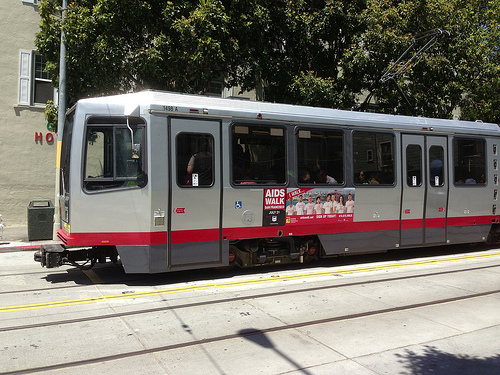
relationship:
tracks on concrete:
[1, 261, 483, 370] [0, 253, 496, 372]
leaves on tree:
[43, 3, 485, 115] [40, 0, 486, 102]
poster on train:
[263, 186, 355, 226] [35, 92, 492, 272]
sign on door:
[191, 170, 199, 188] [167, 115, 223, 267]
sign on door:
[410, 172, 416, 185] [398, 131, 425, 245]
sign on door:
[433, 174, 440, 187] [421, 130, 449, 246]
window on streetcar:
[87, 120, 144, 185] [37, 86, 497, 271]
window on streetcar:
[176, 131, 215, 188] [37, 86, 497, 271]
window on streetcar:
[227, 117, 291, 185] [37, 86, 497, 271]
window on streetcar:
[292, 125, 350, 186] [37, 86, 497, 271]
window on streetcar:
[351, 130, 398, 186] [37, 86, 497, 271]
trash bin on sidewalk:
[25, 199, 55, 243] [6, 233, 100, 246]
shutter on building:
[15, 46, 35, 110] [3, 0, 274, 243]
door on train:
[398, 131, 428, 248] [35, 92, 492, 272]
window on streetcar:
[172, 131, 220, 191] [37, 86, 497, 271]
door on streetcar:
[167, 115, 223, 267] [37, 86, 497, 271]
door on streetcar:
[398, 124, 428, 248] [37, 86, 497, 271]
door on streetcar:
[426, 131, 451, 247] [37, 86, 497, 271]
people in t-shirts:
[297, 195, 330, 212] [285, 201, 298, 212]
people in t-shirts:
[297, 195, 330, 212] [295, 198, 306, 218]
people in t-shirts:
[297, 195, 330, 212] [303, 201, 316, 218]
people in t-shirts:
[297, 195, 330, 212] [315, 202, 324, 216]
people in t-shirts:
[297, 195, 330, 212] [343, 200, 357, 214]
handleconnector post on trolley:
[35, 247, 117, 269] [58, 89, 498, 276]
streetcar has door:
[37, 86, 497, 271] [145, 105, 244, 275]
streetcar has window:
[37, 86, 497, 271] [343, 111, 404, 194]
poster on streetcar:
[263, 186, 355, 226] [37, 86, 497, 271]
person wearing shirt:
[181, 138, 214, 186] [185, 151, 199, 164]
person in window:
[181, 138, 214, 186] [176, 131, 215, 188]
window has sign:
[176, 131, 215, 188] [191, 173, 198, 187]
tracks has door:
[1, 261, 483, 370] [167, 115, 223, 267]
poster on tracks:
[263, 186, 355, 226] [1, 261, 483, 370]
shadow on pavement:
[233, 324, 311, 374] [0, 245, 495, 372]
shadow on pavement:
[398, 340, 498, 372] [0, 245, 495, 372]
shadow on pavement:
[235, 328, 311, 375] [0, 245, 495, 372]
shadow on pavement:
[2, 250, 495, 372] [0, 245, 495, 372]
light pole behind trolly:
[53, 4, 76, 291] [54, 79, 485, 267]